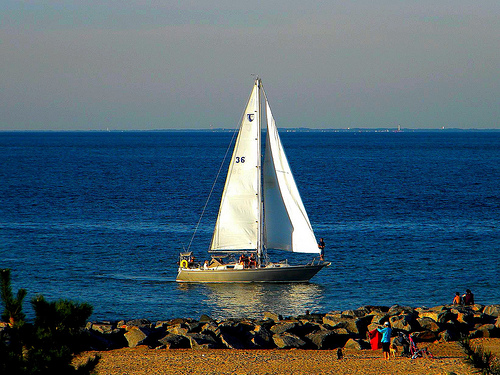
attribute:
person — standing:
[372, 316, 394, 365]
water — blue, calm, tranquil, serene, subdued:
[19, 204, 499, 311]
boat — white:
[165, 76, 337, 293]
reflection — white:
[13, 214, 206, 239]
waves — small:
[30, 233, 178, 295]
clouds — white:
[110, 13, 326, 76]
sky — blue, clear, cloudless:
[17, 14, 482, 118]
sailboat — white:
[235, 71, 322, 289]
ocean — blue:
[14, 129, 497, 304]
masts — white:
[211, 101, 322, 252]